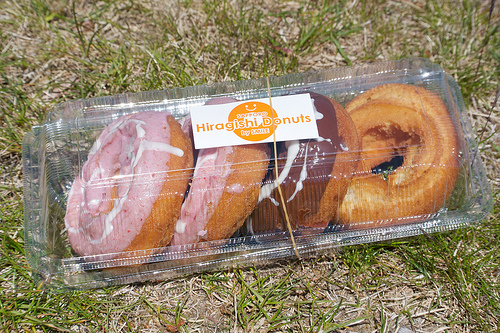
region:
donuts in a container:
[61, 22, 351, 317]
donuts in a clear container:
[28, 45, 493, 289]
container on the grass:
[23, 22, 418, 329]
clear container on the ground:
[12, 20, 443, 328]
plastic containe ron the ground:
[57, 47, 352, 329]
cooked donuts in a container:
[51, 52, 483, 208]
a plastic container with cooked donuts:
[48, 28, 493, 290]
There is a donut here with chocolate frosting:
[273, 140, 292, 203]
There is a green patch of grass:
[277, 290, 294, 324]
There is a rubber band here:
[263, 145, 293, 194]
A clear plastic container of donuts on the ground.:
[1, 2, 499, 332]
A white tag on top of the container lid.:
[190, 92, 317, 152]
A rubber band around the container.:
[264, 80, 302, 263]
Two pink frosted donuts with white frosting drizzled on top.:
[64, 94, 267, 274]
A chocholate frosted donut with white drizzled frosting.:
[242, 88, 359, 245]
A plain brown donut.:
[333, 83, 453, 227]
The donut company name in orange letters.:
[195, 113, 314, 134]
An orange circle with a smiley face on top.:
[228, 101, 278, 143]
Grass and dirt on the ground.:
[0, 0, 499, 332]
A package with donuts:
[25, 175, 57, 242]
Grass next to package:
[29, 295, 65, 312]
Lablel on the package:
[202, 111, 266, 137]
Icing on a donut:
[290, 147, 295, 158]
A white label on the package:
[200, 136, 227, 144]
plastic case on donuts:
[18, 61, 492, 288]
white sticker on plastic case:
[190, 92, 318, 150]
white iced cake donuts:
[47, 98, 254, 259]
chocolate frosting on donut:
[238, 65, 356, 248]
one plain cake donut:
[329, 84, 453, 224]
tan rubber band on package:
[265, 74, 303, 264]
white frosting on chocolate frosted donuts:
[247, 96, 332, 241]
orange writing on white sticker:
[196, 99, 310, 140]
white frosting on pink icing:
[64, 110, 232, 267]